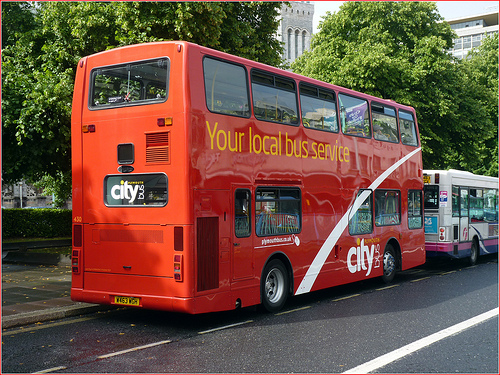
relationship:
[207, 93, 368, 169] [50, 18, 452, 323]
writing on bus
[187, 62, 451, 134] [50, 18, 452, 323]
window of bus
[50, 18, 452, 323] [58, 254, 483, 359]
bus on road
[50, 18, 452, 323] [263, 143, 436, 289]
bus has stripe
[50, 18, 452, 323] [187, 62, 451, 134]
bus has window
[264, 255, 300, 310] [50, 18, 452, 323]
tire of bus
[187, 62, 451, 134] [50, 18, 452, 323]
window on bus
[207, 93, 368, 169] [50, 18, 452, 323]
writing of bus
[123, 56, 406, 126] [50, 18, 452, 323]
top of bus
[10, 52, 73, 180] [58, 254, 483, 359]
trees by road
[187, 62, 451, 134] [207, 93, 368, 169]
window has writing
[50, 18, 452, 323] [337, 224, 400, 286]
bus has brand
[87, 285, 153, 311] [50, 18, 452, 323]
plate of bus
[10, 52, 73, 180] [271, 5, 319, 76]
trees between building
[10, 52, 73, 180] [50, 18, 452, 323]
trees behind bus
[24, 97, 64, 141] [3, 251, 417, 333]
leaves on sidewalk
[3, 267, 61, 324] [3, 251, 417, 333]
drain on sidewalk